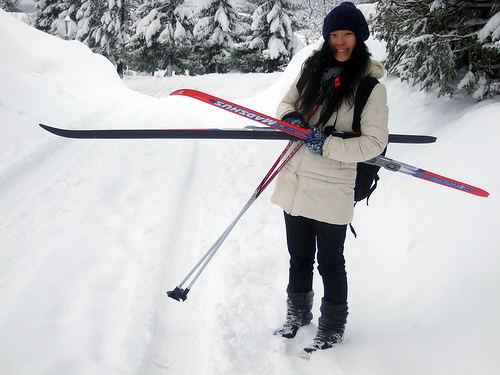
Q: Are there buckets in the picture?
A: No, there are no buckets.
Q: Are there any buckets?
A: No, there are no buckets.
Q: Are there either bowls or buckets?
A: No, there are no buckets or bowls.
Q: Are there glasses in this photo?
A: No, there are no glasses.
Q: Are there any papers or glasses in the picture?
A: No, there are no glasses or papers.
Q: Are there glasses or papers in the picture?
A: No, there are no glasses or papers.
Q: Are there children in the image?
A: No, there are no children.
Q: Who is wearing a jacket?
A: The lady is wearing a jacket.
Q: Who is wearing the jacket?
A: The lady is wearing a jacket.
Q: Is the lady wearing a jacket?
A: Yes, the lady is wearing a jacket.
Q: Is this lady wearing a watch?
A: No, the lady is wearing a jacket.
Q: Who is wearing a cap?
A: The lady is wearing a cap.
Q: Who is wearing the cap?
A: The lady is wearing a cap.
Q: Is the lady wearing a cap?
A: Yes, the lady is wearing a cap.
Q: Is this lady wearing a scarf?
A: No, the lady is wearing a cap.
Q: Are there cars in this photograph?
A: No, there are no cars.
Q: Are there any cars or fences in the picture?
A: No, there are no cars or fences.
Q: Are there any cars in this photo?
A: No, there are no cars.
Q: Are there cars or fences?
A: No, there are no cars or fences.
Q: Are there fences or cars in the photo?
A: No, there are no cars or fences.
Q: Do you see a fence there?
A: No, there are no fences.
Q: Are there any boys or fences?
A: No, there are no fences or boys.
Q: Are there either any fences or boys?
A: No, there are no fences or boys.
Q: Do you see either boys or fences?
A: No, there are no fences or boys.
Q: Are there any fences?
A: No, there are no fences.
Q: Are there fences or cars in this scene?
A: No, there are no fences or cars.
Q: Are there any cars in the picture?
A: No, there are no cars.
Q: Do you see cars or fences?
A: No, there are no cars or fences.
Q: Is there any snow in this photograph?
A: Yes, there is snow.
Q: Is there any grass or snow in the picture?
A: Yes, there is snow.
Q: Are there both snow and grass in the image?
A: No, there is snow but no grass.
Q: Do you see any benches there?
A: No, there are no benches.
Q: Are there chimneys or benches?
A: No, there are no benches or chimneys.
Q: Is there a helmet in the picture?
A: No, there are no helmets.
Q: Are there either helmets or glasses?
A: No, there are no helmets or glasses.